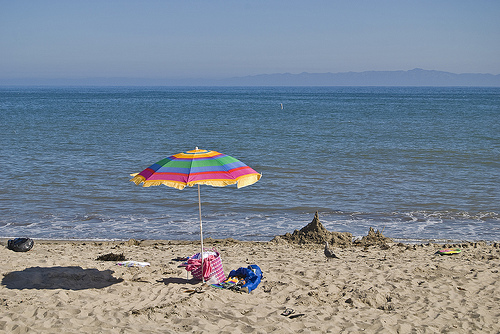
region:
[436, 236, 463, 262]
boogie board in the sand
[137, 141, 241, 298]
umbrella in the sand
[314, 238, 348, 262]
seagull in the sand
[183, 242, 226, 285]
beach bag under the umbrella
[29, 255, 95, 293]
umbrella shadow in the sand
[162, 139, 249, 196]
umbrella is yellow, pink, blue and green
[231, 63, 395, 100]
land on the other side of water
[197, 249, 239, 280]
beach bag is pink and white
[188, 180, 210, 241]
umbrella pole is white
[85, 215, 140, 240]
water coming ashore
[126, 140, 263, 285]
multi-color beach umbrella in the sand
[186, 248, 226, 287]
pink and white beach bag under an umbrella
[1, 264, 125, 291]
shadow of the beach umbrella on the sand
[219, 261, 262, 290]
blue backpack on the sand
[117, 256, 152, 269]
beach towel on the sand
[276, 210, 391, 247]
sand castle near the water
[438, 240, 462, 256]
boogie board on the sand near the water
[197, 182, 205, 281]
pole of the beach umbrella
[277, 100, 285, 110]
buoy in the water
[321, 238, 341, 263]
seagull walking on the beach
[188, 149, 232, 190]
edge of an umbrella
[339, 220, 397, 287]
edge of a shore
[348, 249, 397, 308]
part of a beach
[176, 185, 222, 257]
part of a stand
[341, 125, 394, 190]
part ofv a wter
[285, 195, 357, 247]
part of a sand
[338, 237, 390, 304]
par tof as tand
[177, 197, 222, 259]
part of a metal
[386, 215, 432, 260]
edge of a shore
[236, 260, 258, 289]
part of a metal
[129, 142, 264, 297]
an opened umbrella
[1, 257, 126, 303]
the shadow in the sand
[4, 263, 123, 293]
the shadow from the umbrella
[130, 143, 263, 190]
the colorful umbrella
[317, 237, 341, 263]
the bird on the sand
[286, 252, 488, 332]
the sand at the beach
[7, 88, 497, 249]
the body of water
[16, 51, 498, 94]
the mountains in the distance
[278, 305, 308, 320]
a pair of slippers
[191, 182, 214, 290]
the pole for the umbrella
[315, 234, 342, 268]
seagull standing on the beach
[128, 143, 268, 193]
beach umbrella composed of different colors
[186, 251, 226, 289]
red checkered beach bag on the sand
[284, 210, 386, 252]
remains of a sand castle on water's edge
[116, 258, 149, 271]
material laying on the sand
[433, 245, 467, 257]
colorful item laying on the beach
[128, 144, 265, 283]
striped beach umbrella planted in the sand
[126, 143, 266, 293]
beach supplies underneath an umbrella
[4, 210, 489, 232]
small waves crashing on the shoreline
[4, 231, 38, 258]
dark colored object lying on the beach